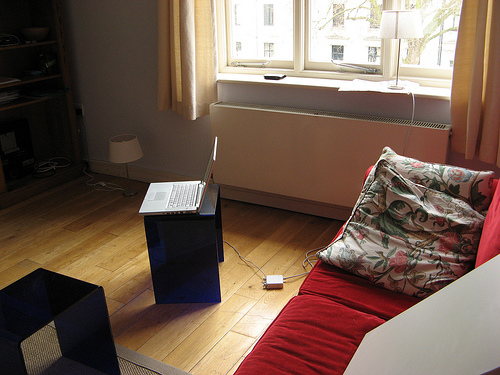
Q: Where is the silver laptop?
A: On the table.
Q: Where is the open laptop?
A: On the table.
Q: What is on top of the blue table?
A: A laptop.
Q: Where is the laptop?
A: On top of a table.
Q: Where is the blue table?
A: On the floor.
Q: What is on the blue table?
A: A laptop.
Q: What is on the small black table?
A: Laptop.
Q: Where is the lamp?
A: On the floor.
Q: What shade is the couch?
A: Red.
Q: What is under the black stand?
A: Gray rug.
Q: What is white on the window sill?
A: Lamp.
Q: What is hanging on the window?
A: Curtains.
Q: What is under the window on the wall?
A: Radiator.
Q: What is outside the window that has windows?
A: Building.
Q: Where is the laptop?
A: On a stand.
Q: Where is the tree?
A: Out the window.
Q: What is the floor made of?
A: Wood.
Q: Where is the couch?
A: To the right.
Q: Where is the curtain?
A: On the window.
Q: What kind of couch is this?
A: Red.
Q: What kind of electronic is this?
A: A laptop.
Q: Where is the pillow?
A: On the couch.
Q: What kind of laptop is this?
A: Silver.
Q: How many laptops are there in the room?
A: 1.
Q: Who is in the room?
A: No one.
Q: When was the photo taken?
A: Day time.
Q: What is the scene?
A: A living room.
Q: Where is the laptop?
A: On a stand.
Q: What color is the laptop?
A: White.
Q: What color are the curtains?
A: Cream.